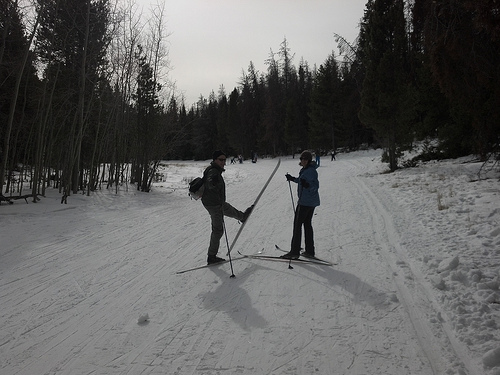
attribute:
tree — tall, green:
[334, 0, 422, 171]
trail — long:
[336, 159, 486, 374]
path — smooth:
[1, 161, 487, 374]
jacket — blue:
[294, 160, 320, 205]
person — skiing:
[329, 149, 337, 162]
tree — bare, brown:
[72, 1, 91, 197]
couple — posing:
[201, 151, 320, 264]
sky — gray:
[6, 1, 421, 118]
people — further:
[230, 151, 337, 165]